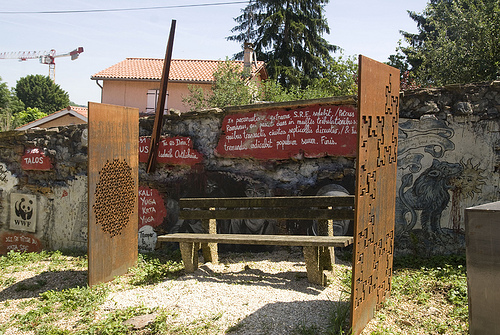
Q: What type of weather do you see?
A: It is sunny.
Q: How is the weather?
A: It is sunny.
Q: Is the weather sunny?
A: Yes, it is sunny.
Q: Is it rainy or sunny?
A: It is sunny.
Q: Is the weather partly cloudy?
A: No, it is sunny.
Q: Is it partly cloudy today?
A: No, it is sunny.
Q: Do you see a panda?
A: Yes, there is a panda.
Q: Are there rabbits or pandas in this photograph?
A: Yes, there is a panda.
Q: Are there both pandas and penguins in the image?
A: No, there is a panda but no penguins.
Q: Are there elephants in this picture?
A: No, there are no elephants.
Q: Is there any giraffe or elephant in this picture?
A: No, there are no elephants or giraffes.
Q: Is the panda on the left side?
A: Yes, the panda is on the left of the image.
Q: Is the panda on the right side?
A: No, the panda is on the left of the image.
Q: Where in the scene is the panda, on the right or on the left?
A: The panda is on the left of the image.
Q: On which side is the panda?
A: The panda is on the left of the image.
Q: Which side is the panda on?
A: The panda is on the left of the image.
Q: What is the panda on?
A: The panda is on the sign.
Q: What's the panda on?
A: The panda is on the sign.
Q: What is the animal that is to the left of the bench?
A: The animal is a panda.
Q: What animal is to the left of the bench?
A: The animal is a panda.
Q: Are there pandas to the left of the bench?
A: Yes, there is a panda to the left of the bench.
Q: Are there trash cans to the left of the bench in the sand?
A: No, there is a panda to the left of the bench.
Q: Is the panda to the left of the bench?
A: Yes, the panda is to the left of the bench.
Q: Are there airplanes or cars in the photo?
A: No, there are no cars or airplanes.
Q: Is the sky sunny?
A: Yes, the sky is sunny.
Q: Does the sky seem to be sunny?
A: Yes, the sky is sunny.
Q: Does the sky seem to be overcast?
A: No, the sky is sunny.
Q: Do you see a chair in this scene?
A: No, there are no chairs.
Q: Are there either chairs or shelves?
A: No, there are no chairs or shelves.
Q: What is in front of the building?
A: The wall is in front of the building.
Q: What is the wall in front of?
A: The wall is in front of the building.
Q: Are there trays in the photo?
A: No, there are no trays.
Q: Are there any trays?
A: No, there are no trays.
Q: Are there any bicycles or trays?
A: No, there are no trays or bicycles.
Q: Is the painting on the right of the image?
A: Yes, the painting is on the right of the image.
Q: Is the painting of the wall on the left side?
A: No, the painting is on the right of the image.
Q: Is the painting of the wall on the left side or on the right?
A: The painting is on the right of the image.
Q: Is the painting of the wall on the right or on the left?
A: The painting is on the right of the image.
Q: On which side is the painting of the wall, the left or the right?
A: The painting is on the right of the image.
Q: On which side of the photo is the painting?
A: The painting is on the right of the image.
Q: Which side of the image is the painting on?
A: The painting is on the right of the image.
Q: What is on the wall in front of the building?
A: The painting is on the wall.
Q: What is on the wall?
A: The painting is on the wall.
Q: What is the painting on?
A: The painting is on the wall.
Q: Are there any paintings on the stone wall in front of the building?
A: Yes, there is a painting on the wall.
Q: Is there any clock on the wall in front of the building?
A: No, there is a painting on the wall.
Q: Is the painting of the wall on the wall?
A: Yes, the painting is on the wall.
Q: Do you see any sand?
A: Yes, there is sand.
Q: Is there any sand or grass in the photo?
A: Yes, there is sand.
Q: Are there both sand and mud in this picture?
A: No, there is sand but no mud.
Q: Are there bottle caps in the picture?
A: No, there are no bottle caps.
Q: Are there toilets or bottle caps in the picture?
A: No, there are no bottle caps or toilets.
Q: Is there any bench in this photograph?
A: Yes, there is a bench.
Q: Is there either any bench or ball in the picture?
A: Yes, there is a bench.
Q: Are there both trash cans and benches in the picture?
A: No, there is a bench but no trash cans.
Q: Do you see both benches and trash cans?
A: No, there is a bench but no trash cans.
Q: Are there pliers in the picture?
A: No, there are no pliers.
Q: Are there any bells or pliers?
A: No, there are no pliers or bells.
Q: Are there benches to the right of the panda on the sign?
A: Yes, there is a bench to the right of the panda bear.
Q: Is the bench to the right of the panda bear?
A: Yes, the bench is to the right of the panda bear.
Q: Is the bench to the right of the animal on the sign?
A: Yes, the bench is to the right of the panda bear.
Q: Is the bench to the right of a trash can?
A: No, the bench is to the right of the panda bear.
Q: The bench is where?
A: The bench is in the sand.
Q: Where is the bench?
A: The bench is in the sand.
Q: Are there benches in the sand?
A: Yes, there is a bench in the sand.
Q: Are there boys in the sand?
A: No, there is a bench in the sand.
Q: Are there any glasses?
A: No, there are no glasses.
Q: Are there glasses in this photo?
A: No, there are no glasses.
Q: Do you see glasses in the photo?
A: No, there are no glasses.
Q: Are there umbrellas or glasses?
A: No, there are no glasses or umbrellas.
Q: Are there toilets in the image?
A: No, there are no toilets.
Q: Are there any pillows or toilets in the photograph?
A: No, there are no toilets or pillows.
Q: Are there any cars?
A: No, there are no cars.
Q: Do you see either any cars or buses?
A: No, there are no cars or buses.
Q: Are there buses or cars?
A: No, there are no cars or buses.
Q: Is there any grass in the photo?
A: Yes, there is grass.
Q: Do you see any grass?
A: Yes, there is grass.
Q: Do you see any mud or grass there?
A: Yes, there is grass.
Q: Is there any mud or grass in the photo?
A: Yes, there is grass.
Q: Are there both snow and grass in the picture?
A: No, there is grass but no snow.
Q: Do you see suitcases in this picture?
A: No, there are no suitcases.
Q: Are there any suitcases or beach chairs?
A: No, there are no suitcases or beach chairs.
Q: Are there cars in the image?
A: No, there are no cars.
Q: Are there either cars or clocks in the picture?
A: No, there are no cars or clocks.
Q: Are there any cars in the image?
A: No, there are no cars.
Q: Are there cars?
A: No, there are no cars.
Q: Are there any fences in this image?
A: Yes, there is a fence.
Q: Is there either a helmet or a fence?
A: Yes, there is a fence.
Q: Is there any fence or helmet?
A: Yes, there is a fence.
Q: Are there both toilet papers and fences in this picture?
A: No, there is a fence but no toilet papers.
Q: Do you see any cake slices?
A: No, there are no cake slices.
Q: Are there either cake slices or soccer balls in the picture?
A: No, there are no cake slices or soccer balls.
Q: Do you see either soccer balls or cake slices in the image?
A: No, there are no cake slices or soccer balls.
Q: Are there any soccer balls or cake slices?
A: No, there are no cake slices or soccer balls.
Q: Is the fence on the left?
A: Yes, the fence is on the left of the image.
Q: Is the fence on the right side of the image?
A: No, the fence is on the left of the image.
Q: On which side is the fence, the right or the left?
A: The fence is on the left of the image.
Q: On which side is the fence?
A: The fence is on the left of the image.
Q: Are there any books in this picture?
A: No, there are no books.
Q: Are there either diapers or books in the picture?
A: No, there are no books or diapers.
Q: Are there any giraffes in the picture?
A: No, there are no giraffes.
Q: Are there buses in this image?
A: No, there are no buses.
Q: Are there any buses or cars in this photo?
A: No, there are no buses or cars.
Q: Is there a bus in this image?
A: No, there are no buses.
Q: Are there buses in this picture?
A: No, there are no buses.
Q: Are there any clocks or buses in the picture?
A: No, there are no buses or clocks.